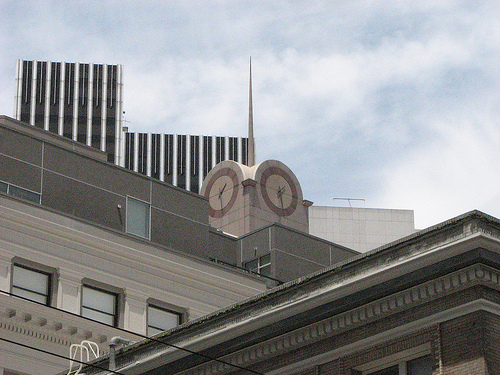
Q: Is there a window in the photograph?
A: Yes, there are windows.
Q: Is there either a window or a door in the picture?
A: Yes, there are windows.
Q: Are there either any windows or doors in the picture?
A: Yes, there are windows.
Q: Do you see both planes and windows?
A: No, there are windows but no airplanes.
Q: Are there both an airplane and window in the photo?
A: No, there are windows but no airplanes.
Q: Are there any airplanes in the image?
A: No, there are no airplanes.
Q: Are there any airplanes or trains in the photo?
A: No, there are no airplanes or trains.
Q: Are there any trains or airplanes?
A: No, there are no airplanes or trains.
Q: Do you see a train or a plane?
A: No, there are no airplanes or trains.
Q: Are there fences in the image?
A: No, there are no fences.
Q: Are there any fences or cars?
A: No, there are no fences or cars.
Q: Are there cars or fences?
A: No, there are no fences or cars.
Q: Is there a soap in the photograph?
A: No, there are no soaps.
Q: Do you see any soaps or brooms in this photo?
A: No, there are no soaps or brooms.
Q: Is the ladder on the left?
A: Yes, the ladder is on the left of the image.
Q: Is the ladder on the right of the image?
A: No, the ladder is on the left of the image.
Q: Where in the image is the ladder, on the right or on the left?
A: The ladder is on the left of the image.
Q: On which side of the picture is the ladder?
A: The ladder is on the left of the image.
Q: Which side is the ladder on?
A: The ladder is on the left of the image.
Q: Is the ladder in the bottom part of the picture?
A: Yes, the ladder is in the bottom of the image.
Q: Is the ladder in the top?
A: No, the ladder is in the bottom of the image.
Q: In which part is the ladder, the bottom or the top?
A: The ladder is in the bottom of the image.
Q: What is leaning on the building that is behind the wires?
A: The ladder is leaning on the building.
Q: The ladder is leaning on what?
A: The ladder is leaning on the building.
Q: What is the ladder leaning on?
A: The ladder is leaning on the building.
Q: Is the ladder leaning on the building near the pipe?
A: Yes, the ladder is leaning on the building.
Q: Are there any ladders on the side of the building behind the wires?
A: Yes, there is a ladder on the side of the building.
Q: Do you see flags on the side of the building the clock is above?
A: No, there is a ladder on the side of the building.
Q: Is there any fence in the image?
A: No, there are no fences.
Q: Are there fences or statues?
A: No, there are no fences or statues.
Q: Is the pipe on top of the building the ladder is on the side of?
A: Yes, the pipe is on top of the building.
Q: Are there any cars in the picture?
A: No, there are no cars.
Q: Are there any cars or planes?
A: No, there are no cars or planes.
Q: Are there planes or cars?
A: No, there are no cars or planes.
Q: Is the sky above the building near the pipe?
A: Yes, the sky is above the building.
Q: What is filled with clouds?
A: The sky is filled with clouds.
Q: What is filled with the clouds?
A: The sky is filled with clouds.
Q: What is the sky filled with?
A: The sky is filled with clouds.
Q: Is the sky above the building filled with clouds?
A: Yes, the sky is filled with clouds.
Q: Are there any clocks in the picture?
A: Yes, there is a clock.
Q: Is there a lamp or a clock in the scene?
A: Yes, there is a clock.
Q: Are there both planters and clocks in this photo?
A: No, there is a clock but no planters.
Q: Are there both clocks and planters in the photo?
A: No, there is a clock but no planters.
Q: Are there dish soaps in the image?
A: No, there are no dish soaps.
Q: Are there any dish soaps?
A: No, there are no dish soaps.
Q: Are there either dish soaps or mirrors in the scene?
A: No, there are no dish soaps or mirrors.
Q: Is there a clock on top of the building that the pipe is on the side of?
A: Yes, there is a clock on top of the building.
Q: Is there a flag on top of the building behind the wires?
A: No, there is a clock on top of the building.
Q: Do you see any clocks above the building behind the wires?
A: Yes, there is a clock above the building.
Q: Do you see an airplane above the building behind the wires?
A: No, there is a clock above the building.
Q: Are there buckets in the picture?
A: No, there are no buckets.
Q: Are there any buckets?
A: No, there are no buckets.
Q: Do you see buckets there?
A: No, there are no buckets.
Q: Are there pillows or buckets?
A: No, there are no buckets or pillows.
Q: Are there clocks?
A: Yes, there is a clock.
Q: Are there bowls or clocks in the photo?
A: Yes, there is a clock.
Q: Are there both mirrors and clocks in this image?
A: No, there is a clock but no mirrors.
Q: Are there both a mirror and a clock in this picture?
A: No, there is a clock but no mirrors.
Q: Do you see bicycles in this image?
A: No, there are no bicycles.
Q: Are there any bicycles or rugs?
A: No, there are no bicycles or rugs.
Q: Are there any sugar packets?
A: No, there are no sugar packets.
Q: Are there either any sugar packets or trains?
A: No, there are no sugar packets or trains.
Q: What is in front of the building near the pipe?
A: The wires are in front of the building.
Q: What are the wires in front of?
A: The wires are in front of the building.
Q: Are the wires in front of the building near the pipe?
A: Yes, the wires are in front of the building.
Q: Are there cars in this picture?
A: No, there are no cars.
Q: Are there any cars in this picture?
A: No, there are no cars.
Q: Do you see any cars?
A: No, there are no cars.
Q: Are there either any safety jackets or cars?
A: No, there are no cars or safety jackets.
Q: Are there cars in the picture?
A: No, there are no cars.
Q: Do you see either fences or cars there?
A: No, there are no cars or fences.